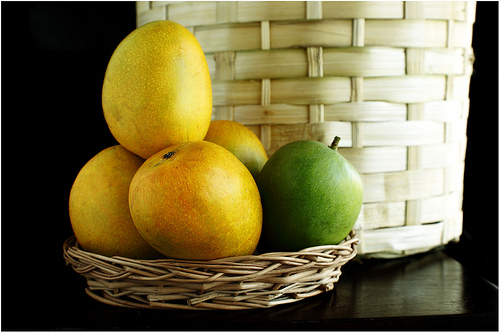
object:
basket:
[62, 231, 360, 311]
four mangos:
[66, 19, 270, 259]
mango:
[99, 19, 214, 159]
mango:
[127, 139, 264, 262]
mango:
[256, 136, 366, 252]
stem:
[329, 135, 342, 150]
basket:
[134, 0, 477, 259]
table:
[4, 219, 497, 326]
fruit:
[67, 142, 151, 260]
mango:
[202, 120, 270, 181]